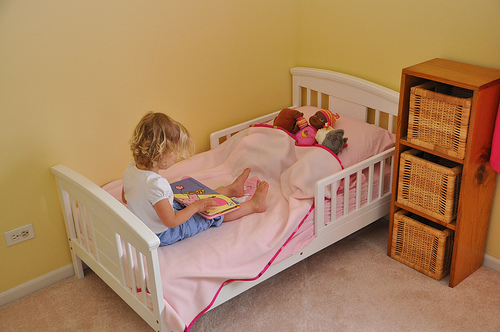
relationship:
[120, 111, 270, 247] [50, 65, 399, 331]
girl sitting on bed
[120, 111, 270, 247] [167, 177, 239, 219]
girl reading book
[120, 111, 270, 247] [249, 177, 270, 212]
girl has foot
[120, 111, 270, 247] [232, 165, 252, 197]
girl has foot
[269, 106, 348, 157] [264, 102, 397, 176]
stuffed animals on top of pillow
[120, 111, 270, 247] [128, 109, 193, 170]
girl has head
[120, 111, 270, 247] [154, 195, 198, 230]
girl has arm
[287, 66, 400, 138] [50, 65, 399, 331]
headboard of bed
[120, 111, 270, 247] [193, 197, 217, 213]
girl has hand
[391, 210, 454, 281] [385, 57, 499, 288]
basket inside shelving unit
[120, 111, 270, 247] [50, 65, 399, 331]
girl reading in bed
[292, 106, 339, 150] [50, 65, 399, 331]
baby doll laying on bed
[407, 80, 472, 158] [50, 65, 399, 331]
basket next to bed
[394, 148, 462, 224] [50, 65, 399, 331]
basket next to bed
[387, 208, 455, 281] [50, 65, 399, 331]
basket next to bed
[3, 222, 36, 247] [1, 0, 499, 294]
outlet attached to walls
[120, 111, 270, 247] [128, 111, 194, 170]
girl has hair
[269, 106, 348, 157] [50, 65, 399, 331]
stuffed animals tucked into bed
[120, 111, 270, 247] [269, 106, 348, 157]
girl has stuffed animals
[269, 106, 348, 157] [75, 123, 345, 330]
stuffed animals underneath blanket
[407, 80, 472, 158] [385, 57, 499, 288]
basket inside shelving unit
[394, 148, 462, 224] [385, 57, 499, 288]
basket inside shelving unit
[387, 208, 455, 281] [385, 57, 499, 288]
basket inside shelving unit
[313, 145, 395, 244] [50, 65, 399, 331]
railing on side of bed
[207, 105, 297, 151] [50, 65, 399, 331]
railing on side of bed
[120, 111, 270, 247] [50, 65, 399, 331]
girl on top of bed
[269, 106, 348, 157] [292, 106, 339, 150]
stuffed animals and baby doll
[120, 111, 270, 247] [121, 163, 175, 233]
girl wearing shirt